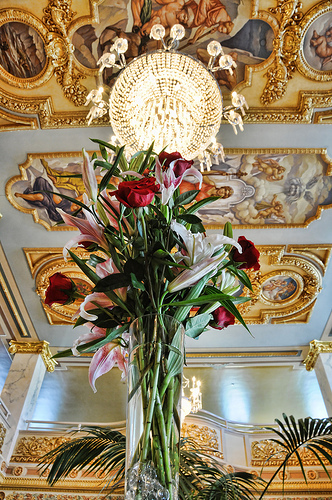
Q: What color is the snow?
A: White.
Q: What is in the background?
A: Trees.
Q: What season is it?
A: Winter.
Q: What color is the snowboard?
A: White.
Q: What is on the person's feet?
A: A snowboard.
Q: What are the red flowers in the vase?
A: Roses.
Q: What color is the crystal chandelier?
A: Cream colored.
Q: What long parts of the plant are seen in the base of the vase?
A: Stems.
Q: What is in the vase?
A: Flowers.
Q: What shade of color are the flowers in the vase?
A: Red, pink and white.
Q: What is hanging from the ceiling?
A: Chandelier.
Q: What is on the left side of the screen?
A: Pillar.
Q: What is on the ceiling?
A: A painting.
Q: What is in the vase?
A: Flowers.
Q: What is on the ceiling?
A: Religious pictures.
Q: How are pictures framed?
A: In ornate gold.